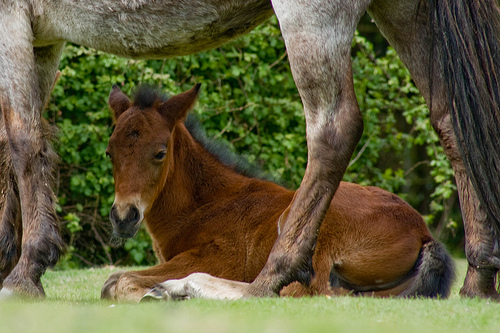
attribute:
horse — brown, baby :
[89, 82, 458, 300]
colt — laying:
[94, 81, 464, 299]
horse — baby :
[82, 74, 466, 310]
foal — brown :
[97, 74, 464, 308]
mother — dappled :
[1, 2, 498, 302]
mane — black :
[135, 70, 284, 192]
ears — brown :
[104, 82, 201, 117]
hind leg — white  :
[165, 238, 416, 292]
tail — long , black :
[423, 5, 498, 237]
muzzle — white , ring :
[96, 167, 156, 239]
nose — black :
[105, 201, 145, 237]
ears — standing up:
[101, 81, 201, 122]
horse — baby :
[80, 65, 457, 297]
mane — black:
[130, 81, 272, 180]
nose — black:
[108, 205, 140, 231]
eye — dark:
[149, 150, 170, 161]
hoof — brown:
[0, 268, 50, 302]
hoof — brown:
[245, 260, 308, 298]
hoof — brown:
[456, 262, 498, 299]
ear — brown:
[156, 80, 197, 128]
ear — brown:
[105, 81, 134, 119]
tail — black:
[402, 238, 456, 298]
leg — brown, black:
[0, 2, 72, 266]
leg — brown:
[1, 161, 20, 277]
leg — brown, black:
[267, 0, 370, 282]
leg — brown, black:
[362, 0, 498, 275]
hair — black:
[130, 81, 286, 188]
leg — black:
[0, 118, 24, 278]